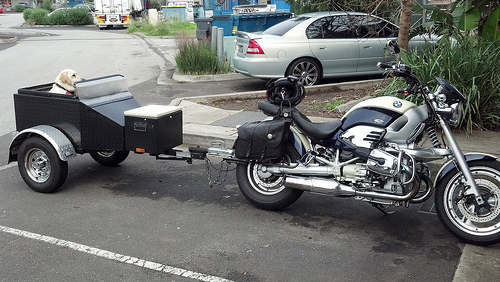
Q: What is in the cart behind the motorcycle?
A: A dog.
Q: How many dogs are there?
A: 1.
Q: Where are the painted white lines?
A: On the pavement.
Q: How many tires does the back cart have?
A: 2.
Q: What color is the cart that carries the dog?
A: Black.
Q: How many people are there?
A: None.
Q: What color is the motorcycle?
A: Black and tan.